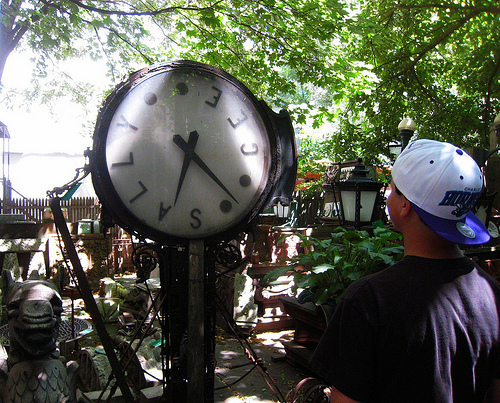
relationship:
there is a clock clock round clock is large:
[89, 58, 291, 398] [88, 60, 284, 246]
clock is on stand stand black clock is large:
[89, 58, 291, 398] [88, 60, 284, 246]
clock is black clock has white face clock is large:
[89, 60, 298, 246] [88, 60, 284, 246]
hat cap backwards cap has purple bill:
[389, 138, 490, 248] [409, 205, 489, 249]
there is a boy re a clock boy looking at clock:
[306, 138, 500, 399] [91, 60, 497, 400]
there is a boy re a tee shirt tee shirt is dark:
[306, 138, 500, 399] [304, 253, 499, 400]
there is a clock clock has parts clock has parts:
[89, 58, 291, 398] [250, 88, 299, 215]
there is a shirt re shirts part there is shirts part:
[304, 253, 499, 400] [303, 269, 378, 397]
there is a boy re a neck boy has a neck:
[306, 138, 500, 399] [397, 221, 471, 262]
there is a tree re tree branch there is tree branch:
[0, 1, 498, 174] [38, 0, 309, 64]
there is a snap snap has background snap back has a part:
[2, 1, 499, 401] [1, 3, 396, 262]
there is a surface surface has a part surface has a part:
[89, 60, 298, 246] [202, 77, 267, 171]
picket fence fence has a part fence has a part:
[0, 196, 103, 223] [27, 199, 44, 228]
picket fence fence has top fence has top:
[0, 196, 103, 223] [1, 197, 100, 209]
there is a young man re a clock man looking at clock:
[306, 138, 500, 399] [91, 60, 497, 400]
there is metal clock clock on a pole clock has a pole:
[89, 58, 291, 398] [148, 245, 220, 402]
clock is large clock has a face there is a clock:
[88, 60, 284, 246] [89, 58, 291, 398]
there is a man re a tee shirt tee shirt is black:
[306, 138, 500, 399] [304, 253, 499, 400]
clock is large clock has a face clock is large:
[89, 60, 298, 246] [88, 60, 284, 246]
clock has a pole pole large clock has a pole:
[89, 58, 291, 398] [148, 245, 220, 402]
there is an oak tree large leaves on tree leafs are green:
[0, 1, 498, 174] [314, 1, 499, 127]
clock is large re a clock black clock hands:
[88, 60, 284, 246] [171, 127, 242, 205]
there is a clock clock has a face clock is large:
[89, 58, 291, 398] [88, 60, 284, 246]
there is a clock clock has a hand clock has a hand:
[89, 58, 291, 398] [166, 128, 202, 207]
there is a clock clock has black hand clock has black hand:
[89, 58, 291, 398] [171, 127, 242, 205]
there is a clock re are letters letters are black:
[89, 58, 291, 398] [111, 87, 260, 230]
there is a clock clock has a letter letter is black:
[89, 58, 291, 398] [203, 86, 222, 110]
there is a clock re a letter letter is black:
[89, 58, 291, 398] [238, 141, 261, 158]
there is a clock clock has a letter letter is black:
[89, 58, 291, 398] [113, 114, 141, 134]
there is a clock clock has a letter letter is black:
[89, 58, 291, 398] [187, 206, 205, 231]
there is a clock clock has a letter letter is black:
[89, 58, 291, 398] [107, 148, 138, 171]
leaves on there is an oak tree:
[197, 3, 498, 137] [295, 1, 499, 215]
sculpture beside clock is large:
[0, 273, 80, 401] [88, 60, 284, 246]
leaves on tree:
[347, 21, 483, 123] [297, 1, 497, 215]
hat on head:
[389, 135, 498, 255] [384, 139, 485, 255]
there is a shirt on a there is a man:
[300, 253, 498, 402] [306, 138, 500, 402]